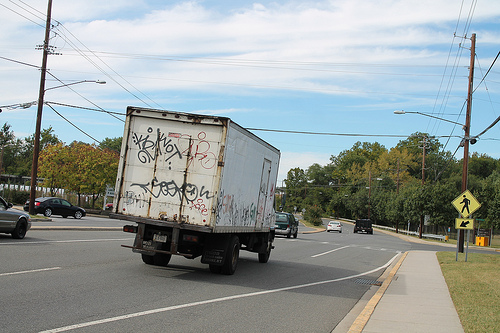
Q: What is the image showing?
A: It is showing a road.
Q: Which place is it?
A: It is a road.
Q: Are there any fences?
A: No, there are no fences.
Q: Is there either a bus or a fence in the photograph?
A: No, there are no fences or buses.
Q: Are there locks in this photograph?
A: No, there are no locks.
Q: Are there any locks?
A: No, there are no locks.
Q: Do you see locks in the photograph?
A: No, there are no locks.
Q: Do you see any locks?
A: No, there are no locks.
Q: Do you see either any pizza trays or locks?
A: No, there are no locks or pizza trays.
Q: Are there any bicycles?
A: No, there are no bicycles.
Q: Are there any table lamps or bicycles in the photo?
A: No, there are no bicycles or table lamps.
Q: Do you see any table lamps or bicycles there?
A: No, there are no bicycles or table lamps.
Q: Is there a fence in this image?
A: No, there are no fences.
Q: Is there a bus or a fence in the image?
A: No, there are no fences or buses.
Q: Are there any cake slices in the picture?
A: No, there are no cake slices.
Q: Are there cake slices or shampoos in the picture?
A: No, there are no cake slices or shampoos.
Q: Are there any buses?
A: No, there are no buses.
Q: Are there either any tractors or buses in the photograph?
A: No, there are no buses or tractors.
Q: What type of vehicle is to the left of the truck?
A: The vehicle is a car.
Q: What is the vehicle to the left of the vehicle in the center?
A: The vehicle is a car.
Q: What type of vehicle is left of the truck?
A: The vehicle is a car.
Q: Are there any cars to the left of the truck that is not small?
A: Yes, there is a car to the left of the truck.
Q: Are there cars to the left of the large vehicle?
A: Yes, there is a car to the left of the truck.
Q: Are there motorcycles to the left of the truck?
A: No, there is a car to the left of the truck.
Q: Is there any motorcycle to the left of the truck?
A: No, there is a car to the left of the truck.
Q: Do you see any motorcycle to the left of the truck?
A: No, there is a car to the left of the truck.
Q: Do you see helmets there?
A: No, there are no helmets.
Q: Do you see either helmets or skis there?
A: No, there are no helmets or skis.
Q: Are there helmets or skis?
A: No, there are no helmets or skis.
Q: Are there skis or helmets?
A: No, there are no helmets or skis.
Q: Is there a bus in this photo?
A: No, there are no buses.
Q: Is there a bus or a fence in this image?
A: No, there are no buses or fences.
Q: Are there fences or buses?
A: No, there are no buses or fences.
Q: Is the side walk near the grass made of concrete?
A: Yes, the sidewalk is made of concrete.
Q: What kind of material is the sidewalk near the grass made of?
A: The sidewalk is made of cement.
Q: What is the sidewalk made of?
A: The sidewalk is made of concrete.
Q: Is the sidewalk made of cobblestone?
A: No, the sidewalk is made of cement.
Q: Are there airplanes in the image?
A: No, there are no airplanes.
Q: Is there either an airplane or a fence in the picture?
A: No, there are no airplanes or fences.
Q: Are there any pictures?
A: No, there are no pictures.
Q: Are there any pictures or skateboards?
A: No, there are no pictures or skateboards.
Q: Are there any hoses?
A: No, there are no hoses.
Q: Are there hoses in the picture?
A: No, there are no hoses.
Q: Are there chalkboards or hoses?
A: No, there are no hoses or chalkboards.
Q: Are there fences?
A: No, there are no fences.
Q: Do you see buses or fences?
A: No, there are no fences or buses.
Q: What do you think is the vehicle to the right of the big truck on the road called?
A: The vehicle is a car.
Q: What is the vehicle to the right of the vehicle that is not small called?
A: The vehicle is a car.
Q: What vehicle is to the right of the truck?
A: The vehicle is a car.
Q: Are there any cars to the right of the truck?
A: Yes, there is a car to the right of the truck.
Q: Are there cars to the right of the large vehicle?
A: Yes, there is a car to the right of the truck.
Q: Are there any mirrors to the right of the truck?
A: No, there is a car to the right of the truck.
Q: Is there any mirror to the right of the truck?
A: No, there is a car to the right of the truck.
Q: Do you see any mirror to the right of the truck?
A: No, there is a car to the right of the truck.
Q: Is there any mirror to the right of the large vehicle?
A: No, there is a car to the right of the truck.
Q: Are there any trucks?
A: Yes, there is a truck.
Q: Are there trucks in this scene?
A: Yes, there is a truck.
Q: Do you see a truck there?
A: Yes, there is a truck.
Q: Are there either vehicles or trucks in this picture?
A: Yes, there is a truck.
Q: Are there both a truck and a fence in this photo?
A: No, there is a truck but no fences.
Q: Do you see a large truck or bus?
A: Yes, there is a large truck.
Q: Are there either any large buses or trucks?
A: Yes, there is a large truck.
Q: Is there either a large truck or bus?
A: Yes, there is a large truck.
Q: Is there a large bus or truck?
A: Yes, there is a large truck.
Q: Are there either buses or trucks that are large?
A: Yes, the truck is large.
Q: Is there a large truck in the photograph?
A: Yes, there is a large truck.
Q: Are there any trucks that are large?
A: Yes, there is a truck that is large.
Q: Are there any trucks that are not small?
A: Yes, there is a large truck.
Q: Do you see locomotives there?
A: No, there are no locomotives.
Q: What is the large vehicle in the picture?
A: The vehicle is a truck.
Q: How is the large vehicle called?
A: The vehicle is a truck.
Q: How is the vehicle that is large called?
A: The vehicle is a truck.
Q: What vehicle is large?
A: The vehicle is a truck.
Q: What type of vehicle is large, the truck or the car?
A: The truck is large.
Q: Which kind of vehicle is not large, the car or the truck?
A: The car is not large.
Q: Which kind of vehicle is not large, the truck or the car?
A: The car is not large.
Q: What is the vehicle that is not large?
A: The vehicle is a car.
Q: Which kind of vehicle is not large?
A: The vehicle is a car.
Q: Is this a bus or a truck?
A: This is a truck.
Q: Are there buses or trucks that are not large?
A: No, there is a truck but it is large.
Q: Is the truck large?
A: Yes, the truck is large.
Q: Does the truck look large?
A: Yes, the truck is large.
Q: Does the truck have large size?
A: Yes, the truck is large.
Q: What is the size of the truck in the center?
A: The truck is large.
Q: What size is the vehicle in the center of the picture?
A: The truck is large.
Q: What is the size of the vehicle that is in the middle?
A: The truck is large.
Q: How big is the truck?
A: The truck is large.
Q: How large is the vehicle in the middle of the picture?
A: The truck is large.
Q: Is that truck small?
A: No, the truck is large.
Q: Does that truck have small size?
A: No, the truck is large.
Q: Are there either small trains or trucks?
A: No, there is a truck but it is large.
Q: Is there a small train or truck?
A: No, there is a truck but it is large.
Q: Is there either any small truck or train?
A: No, there is a truck but it is large.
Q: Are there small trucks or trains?
A: No, there is a truck but it is large.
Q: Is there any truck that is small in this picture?
A: No, there is a truck but it is large.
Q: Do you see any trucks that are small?
A: No, there is a truck but it is large.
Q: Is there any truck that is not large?
A: No, there is a truck but it is large.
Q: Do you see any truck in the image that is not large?
A: No, there is a truck but it is large.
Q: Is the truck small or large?
A: The truck is large.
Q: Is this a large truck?
A: Yes, this is a large truck.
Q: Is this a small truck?
A: No, this is a large truck.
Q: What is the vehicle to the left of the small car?
A: The vehicle is a truck.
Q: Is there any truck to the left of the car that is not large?
A: Yes, there is a truck to the left of the car.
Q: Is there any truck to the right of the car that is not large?
A: No, the truck is to the left of the car.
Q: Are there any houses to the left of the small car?
A: No, there is a truck to the left of the car.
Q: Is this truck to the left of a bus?
A: No, the truck is to the left of the car.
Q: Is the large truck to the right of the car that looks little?
A: No, the truck is to the left of the car.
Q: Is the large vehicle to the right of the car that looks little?
A: No, the truck is to the left of the car.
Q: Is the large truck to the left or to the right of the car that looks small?
A: The truck is to the left of the car.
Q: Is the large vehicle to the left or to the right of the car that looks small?
A: The truck is to the left of the car.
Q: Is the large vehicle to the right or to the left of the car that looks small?
A: The truck is to the left of the car.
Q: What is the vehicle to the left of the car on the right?
A: The vehicle is a truck.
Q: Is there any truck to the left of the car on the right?
A: Yes, there is a truck to the left of the car.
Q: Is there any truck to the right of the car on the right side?
A: No, the truck is to the left of the car.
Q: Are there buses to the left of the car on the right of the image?
A: No, there is a truck to the left of the car.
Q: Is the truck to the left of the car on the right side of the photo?
A: Yes, the truck is to the left of the car.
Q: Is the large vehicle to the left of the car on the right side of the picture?
A: Yes, the truck is to the left of the car.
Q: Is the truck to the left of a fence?
A: No, the truck is to the left of the car.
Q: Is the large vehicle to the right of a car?
A: No, the truck is to the left of a car.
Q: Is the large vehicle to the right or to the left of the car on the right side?
A: The truck is to the left of the car.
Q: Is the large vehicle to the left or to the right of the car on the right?
A: The truck is to the left of the car.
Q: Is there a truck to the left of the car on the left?
A: No, the truck is to the right of the car.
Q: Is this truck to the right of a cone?
A: No, the truck is to the right of the car.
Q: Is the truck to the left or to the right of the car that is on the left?
A: The truck is to the right of the car.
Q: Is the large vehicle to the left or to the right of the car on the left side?
A: The truck is to the right of the car.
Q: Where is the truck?
A: The truck is on the road.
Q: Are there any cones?
A: No, there are no cones.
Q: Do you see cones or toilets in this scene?
A: No, there are no cones or toilets.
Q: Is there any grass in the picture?
A: Yes, there is grass.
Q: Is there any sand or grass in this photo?
A: Yes, there is grass.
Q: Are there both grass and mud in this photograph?
A: No, there is grass but no mud.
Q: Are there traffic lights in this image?
A: No, there are no traffic lights.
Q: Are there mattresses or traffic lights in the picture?
A: No, there are no traffic lights or mattresses.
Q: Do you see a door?
A: Yes, there is a door.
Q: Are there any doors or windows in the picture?
A: Yes, there is a door.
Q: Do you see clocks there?
A: No, there are no clocks.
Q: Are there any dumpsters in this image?
A: No, there are no dumpsters.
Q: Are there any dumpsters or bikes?
A: No, there are no dumpsters or bikes.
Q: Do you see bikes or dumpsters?
A: No, there are no dumpsters or bikes.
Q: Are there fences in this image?
A: No, there are no fences.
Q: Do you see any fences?
A: No, there are no fences.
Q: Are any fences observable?
A: No, there are no fences.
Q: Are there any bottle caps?
A: No, there are no bottle caps.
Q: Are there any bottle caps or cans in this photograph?
A: No, there are no bottle caps or cans.